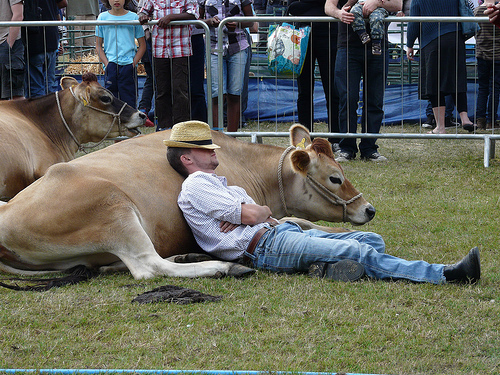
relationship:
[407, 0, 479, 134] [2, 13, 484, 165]
lady behind barriers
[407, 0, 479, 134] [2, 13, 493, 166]
lady standing behind barriers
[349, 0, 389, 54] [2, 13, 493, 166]
boy on barriers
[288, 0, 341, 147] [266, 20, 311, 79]
man holding bag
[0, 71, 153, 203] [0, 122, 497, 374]
brown cow on ground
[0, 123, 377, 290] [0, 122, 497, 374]
cow on ground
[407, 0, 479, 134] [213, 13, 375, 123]
lady in fence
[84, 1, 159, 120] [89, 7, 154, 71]
boy wearing shirt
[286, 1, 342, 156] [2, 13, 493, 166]
person standing behind barriers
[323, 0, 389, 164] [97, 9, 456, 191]
man standing behind fence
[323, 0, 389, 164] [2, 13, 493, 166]
man standing behind barriers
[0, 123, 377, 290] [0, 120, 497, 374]
cow laying on grass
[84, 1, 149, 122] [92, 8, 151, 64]
boy has shirt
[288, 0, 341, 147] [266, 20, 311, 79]
man holds bag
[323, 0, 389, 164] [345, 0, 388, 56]
man holding boy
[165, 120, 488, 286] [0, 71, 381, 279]
man lying on cow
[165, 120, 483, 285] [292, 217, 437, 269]
man wearing jeans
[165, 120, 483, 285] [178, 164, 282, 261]
man wearing shirt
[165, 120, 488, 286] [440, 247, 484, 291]
man wearing boots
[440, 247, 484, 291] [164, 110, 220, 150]
boots wearing hat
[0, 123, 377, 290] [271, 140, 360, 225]
cow wearing halter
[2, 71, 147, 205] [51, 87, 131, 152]
brown cow wearing halter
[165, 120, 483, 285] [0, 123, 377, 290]
man leaning against cow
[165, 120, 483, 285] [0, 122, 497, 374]
man on ground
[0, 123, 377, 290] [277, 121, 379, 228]
cow has head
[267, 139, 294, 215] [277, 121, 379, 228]
rope on head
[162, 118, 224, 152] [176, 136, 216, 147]
fedora has band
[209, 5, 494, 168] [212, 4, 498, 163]
fence has gate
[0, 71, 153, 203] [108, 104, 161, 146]
brown cow has mouth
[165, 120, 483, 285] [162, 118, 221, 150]
man wearing fedora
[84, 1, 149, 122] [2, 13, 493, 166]
boy standing behind barriers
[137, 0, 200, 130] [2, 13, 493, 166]
person standing behind barriers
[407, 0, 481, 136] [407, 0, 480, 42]
lady wearing shirt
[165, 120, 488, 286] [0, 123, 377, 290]
man lying on cow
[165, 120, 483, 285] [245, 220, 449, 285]
man wearing jeans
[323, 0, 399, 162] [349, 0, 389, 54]
man holding boy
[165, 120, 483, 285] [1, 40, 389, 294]
man lying on cows